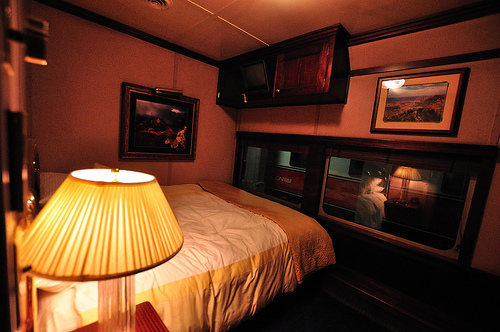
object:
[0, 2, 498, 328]
bedroom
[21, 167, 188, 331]
lamp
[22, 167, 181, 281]
shade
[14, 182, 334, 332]
comforter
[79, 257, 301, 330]
hem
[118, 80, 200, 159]
picture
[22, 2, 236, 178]
wall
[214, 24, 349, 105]
cabinet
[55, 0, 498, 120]
ceiling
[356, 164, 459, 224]
reflection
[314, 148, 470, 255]
window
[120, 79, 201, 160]
frame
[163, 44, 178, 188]
seam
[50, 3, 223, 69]
molding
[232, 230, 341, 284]
blanket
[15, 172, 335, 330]
bed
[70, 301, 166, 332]
side table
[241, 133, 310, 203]
window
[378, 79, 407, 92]
wall lamp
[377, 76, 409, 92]
reflection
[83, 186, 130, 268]
groove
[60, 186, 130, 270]
groove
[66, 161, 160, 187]
light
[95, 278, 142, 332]
base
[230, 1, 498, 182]
wall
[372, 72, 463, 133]
picture